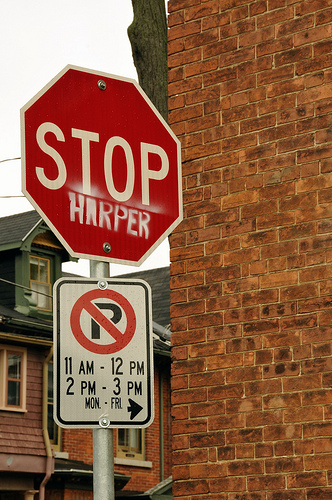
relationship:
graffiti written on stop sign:
[67, 192, 154, 240] [16, 62, 190, 267]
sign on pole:
[52, 277, 153, 429] [91, 429, 114, 498]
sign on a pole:
[24, 56, 186, 268] [91, 260, 113, 499]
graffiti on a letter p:
[67, 192, 154, 240] [67, 286, 137, 354]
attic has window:
[2, 205, 65, 320] [25, 252, 54, 313]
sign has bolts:
[7, 56, 194, 269] [93, 240, 121, 256]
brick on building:
[254, 62, 296, 84] [163, 1, 329, 497]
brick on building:
[165, 0, 331, 498] [163, 1, 329, 497]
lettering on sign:
[81, 394, 124, 411] [52, 277, 153, 429]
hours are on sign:
[67, 358, 144, 421] [52, 277, 153, 429]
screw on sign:
[97, 79, 105, 89] [52, 277, 153, 429]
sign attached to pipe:
[52, 277, 153, 429] [88, 255, 115, 498]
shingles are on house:
[4, 217, 31, 234] [10, 208, 52, 261]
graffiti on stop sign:
[67, 192, 154, 240] [16, 62, 190, 267]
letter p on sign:
[67, 286, 137, 354] [12, 55, 188, 431]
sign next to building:
[24, 56, 186, 268] [163, 1, 329, 497]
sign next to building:
[52, 277, 153, 429] [163, 1, 329, 497]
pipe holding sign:
[88, 255, 115, 498] [52, 277, 153, 429]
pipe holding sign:
[88, 255, 115, 498] [24, 56, 186, 268]